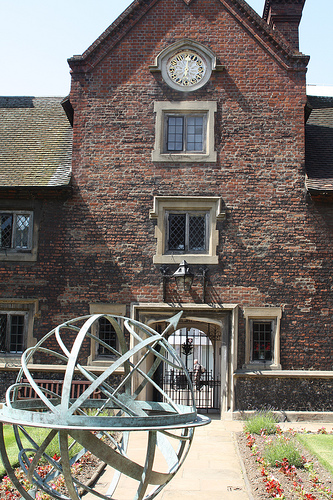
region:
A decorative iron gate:
[159, 329, 228, 418]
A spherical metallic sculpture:
[0, 299, 227, 498]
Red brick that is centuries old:
[236, 199, 323, 294]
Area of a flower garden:
[237, 414, 321, 499]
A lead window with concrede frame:
[148, 192, 226, 264]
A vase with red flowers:
[251, 338, 271, 362]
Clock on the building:
[156, 38, 224, 102]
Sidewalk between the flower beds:
[194, 461, 230, 498]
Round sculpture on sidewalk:
[17, 313, 202, 499]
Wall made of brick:
[274, 275, 325, 330]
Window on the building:
[240, 301, 286, 374]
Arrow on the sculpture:
[151, 299, 182, 341]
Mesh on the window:
[166, 210, 212, 253]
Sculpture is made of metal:
[97, 380, 175, 454]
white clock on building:
[167, 45, 202, 83]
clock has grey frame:
[162, 44, 221, 90]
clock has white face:
[163, 51, 204, 89]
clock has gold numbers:
[165, 51, 203, 98]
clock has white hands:
[169, 50, 207, 98]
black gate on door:
[149, 312, 227, 425]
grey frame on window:
[155, 200, 222, 268]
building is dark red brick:
[78, 68, 289, 365]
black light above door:
[161, 268, 200, 312]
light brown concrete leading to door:
[132, 418, 239, 498]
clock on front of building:
[148, 37, 225, 92]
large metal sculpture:
[0, 309, 212, 499]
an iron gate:
[153, 320, 221, 414]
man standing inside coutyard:
[191, 357, 207, 392]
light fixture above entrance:
[172, 259, 195, 292]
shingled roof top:
[0, 94, 332, 190]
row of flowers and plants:
[233, 405, 331, 499]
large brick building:
[0, 0, 332, 421]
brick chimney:
[261, 0, 307, 54]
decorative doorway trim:
[130, 302, 237, 422]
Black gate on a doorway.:
[155, 321, 221, 413]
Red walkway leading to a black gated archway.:
[113, 409, 250, 498]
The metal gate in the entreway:
[153, 323, 222, 411]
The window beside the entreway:
[249, 316, 273, 363]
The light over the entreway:
[173, 260, 193, 291]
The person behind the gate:
[191, 357, 205, 388]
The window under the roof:
[0, 212, 34, 251]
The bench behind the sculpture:
[10, 376, 103, 400]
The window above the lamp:
[161, 205, 208, 252]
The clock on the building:
[164, 48, 208, 87]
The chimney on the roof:
[262, 1, 306, 53]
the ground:
[204, 445, 224, 472]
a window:
[246, 320, 274, 362]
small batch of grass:
[267, 439, 299, 465]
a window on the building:
[7, 213, 33, 249]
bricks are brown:
[249, 254, 285, 290]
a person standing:
[193, 357, 206, 386]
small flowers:
[267, 473, 278, 498]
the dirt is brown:
[280, 474, 294, 493]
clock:
[164, 43, 203, 88]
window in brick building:
[155, 101, 209, 162]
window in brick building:
[147, 192, 219, 251]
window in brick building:
[239, 313, 274, 360]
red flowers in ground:
[257, 471, 269, 482]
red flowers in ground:
[255, 477, 269, 493]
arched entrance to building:
[159, 322, 215, 399]